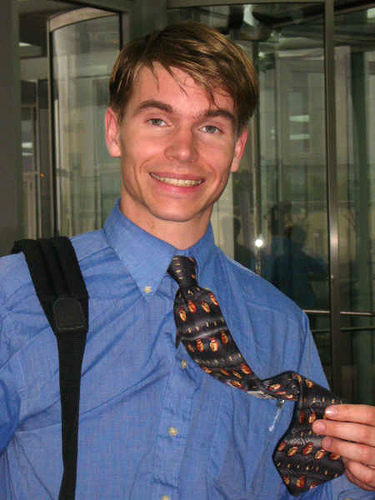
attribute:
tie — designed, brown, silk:
[160, 254, 352, 498]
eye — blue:
[142, 110, 171, 133]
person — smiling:
[4, 15, 343, 477]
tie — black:
[167, 255, 317, 496]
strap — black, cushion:
[18, 237, 96, 346]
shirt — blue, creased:
[2, 237, 365, 494]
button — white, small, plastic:
[143, 285, 152, 295]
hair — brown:
[98, 32, 259, 109]